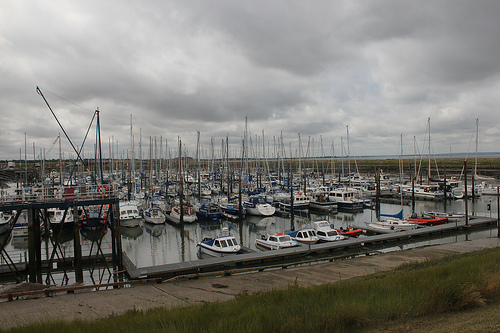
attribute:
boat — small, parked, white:
[195, 233, 257, 261]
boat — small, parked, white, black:
[256, 229, 299, 254]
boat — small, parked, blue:
[286, 225, 321, 245]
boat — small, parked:
[305, 219, 351, 244]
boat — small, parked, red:
[336, 220, 363, 239]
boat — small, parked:
[365, 217, 402, 234]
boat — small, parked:
[375, 215, 417, 229]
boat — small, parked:
[406, 209, 450, 227]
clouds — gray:
[3, 1, 499, 156]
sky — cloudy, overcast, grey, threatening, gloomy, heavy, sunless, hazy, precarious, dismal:
[1, 1, 500, 164]